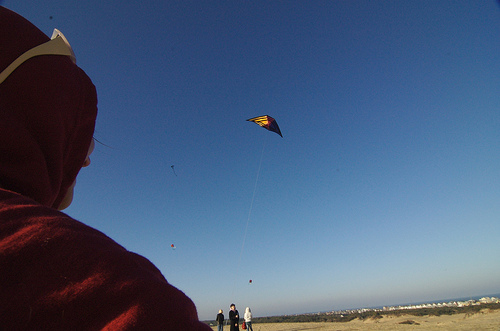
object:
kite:
[245, 113, 285, 138]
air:
[272, 169, 362, 246]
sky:
[0, 0, 499, 322]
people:
[241, 306, 253, 331]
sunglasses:
[0, 28, 80, 86]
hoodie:
[1, 7, 215, 330]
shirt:
[228, 309, 241, 324]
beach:
[199, 309, 500, 330]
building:
[478, 295, 500, 303]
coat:
[242, 305, 252, 322]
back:
[0, 191, 78, 330]